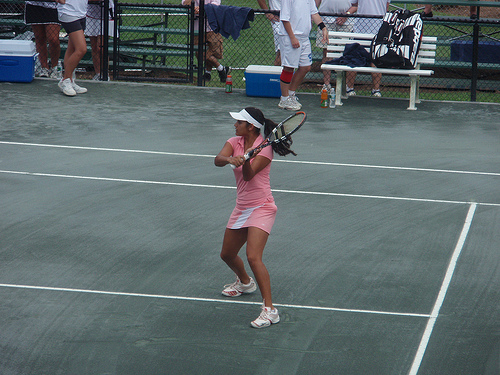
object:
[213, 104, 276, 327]
woman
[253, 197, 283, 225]
pink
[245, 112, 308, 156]
racket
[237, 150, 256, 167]
held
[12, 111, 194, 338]
court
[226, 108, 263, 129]
visor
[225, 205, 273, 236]
skirt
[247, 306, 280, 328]
sneakers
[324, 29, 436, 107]
bench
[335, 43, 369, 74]
bag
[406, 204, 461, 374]
line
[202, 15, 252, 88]
fence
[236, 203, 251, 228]
white stripe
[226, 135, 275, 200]
shirt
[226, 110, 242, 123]
shade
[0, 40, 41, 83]
cooler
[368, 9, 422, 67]
bag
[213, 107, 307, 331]
tennis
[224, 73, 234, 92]
sportsdrink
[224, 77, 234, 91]
bottle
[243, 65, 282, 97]
cooler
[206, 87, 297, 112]
ground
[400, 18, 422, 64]
stripes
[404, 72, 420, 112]
legs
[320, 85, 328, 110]
drink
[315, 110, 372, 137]
ground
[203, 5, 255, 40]
towel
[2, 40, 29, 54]
white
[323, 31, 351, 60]
slats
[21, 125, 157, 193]
lines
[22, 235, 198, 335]
sections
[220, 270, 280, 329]
shoes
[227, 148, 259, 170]
hands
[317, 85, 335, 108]
drinks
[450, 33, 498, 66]
black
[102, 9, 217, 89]
entry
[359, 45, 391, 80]
sit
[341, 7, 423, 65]
bags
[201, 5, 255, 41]
jacket